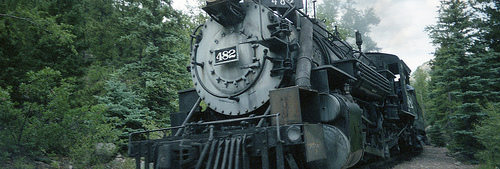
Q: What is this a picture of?
A: A locomotive.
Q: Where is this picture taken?
A: A forest.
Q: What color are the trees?
A: Green.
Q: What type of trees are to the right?
A: Pine.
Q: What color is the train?
A: Black.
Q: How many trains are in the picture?
A: One.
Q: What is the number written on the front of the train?
A: 482.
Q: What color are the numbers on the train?
A: White.